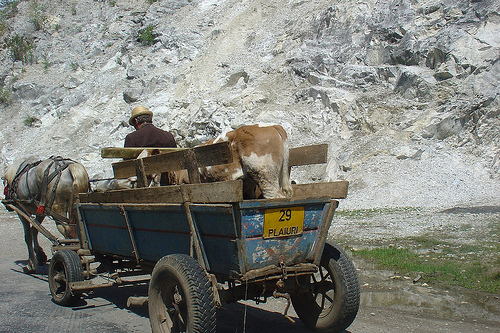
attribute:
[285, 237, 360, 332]
wheel — bent, wagon's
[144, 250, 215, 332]
wheel — bent, wagon's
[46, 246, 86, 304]
wheel — bent, wagon's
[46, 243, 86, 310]
wheel — black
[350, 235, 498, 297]
grass — green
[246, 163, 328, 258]
sign — yellow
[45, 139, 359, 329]
cart — blue, wooden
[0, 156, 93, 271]
horse — brown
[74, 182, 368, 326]
wagon — blue, wooden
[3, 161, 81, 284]
horse — white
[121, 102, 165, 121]
hat — gold, top hat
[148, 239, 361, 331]
wheel — rubber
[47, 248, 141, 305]
wheel — rubber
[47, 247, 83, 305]
wheel — rubber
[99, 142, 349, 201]
fence — wooden